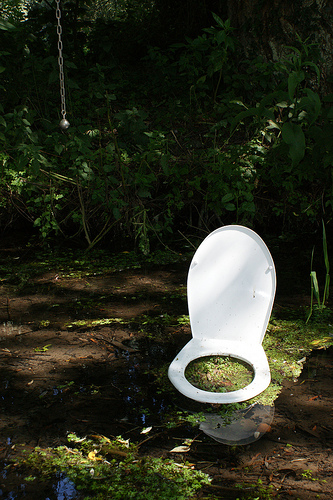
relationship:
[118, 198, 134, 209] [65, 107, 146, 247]
leaf of tree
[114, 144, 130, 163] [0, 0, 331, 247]
leaf of tree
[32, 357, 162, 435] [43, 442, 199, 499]
water puddle by grass.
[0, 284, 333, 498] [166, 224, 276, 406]
water surrounding toilet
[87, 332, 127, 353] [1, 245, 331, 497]
twig lying on dirt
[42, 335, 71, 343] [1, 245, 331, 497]
twig lying on dirt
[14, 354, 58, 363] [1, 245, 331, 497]
twig lying on dirt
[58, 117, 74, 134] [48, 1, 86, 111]
ball on chain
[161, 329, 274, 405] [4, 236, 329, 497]
toilet seat on ground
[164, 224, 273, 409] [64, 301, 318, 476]
toilet in garden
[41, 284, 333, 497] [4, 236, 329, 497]
water on ground